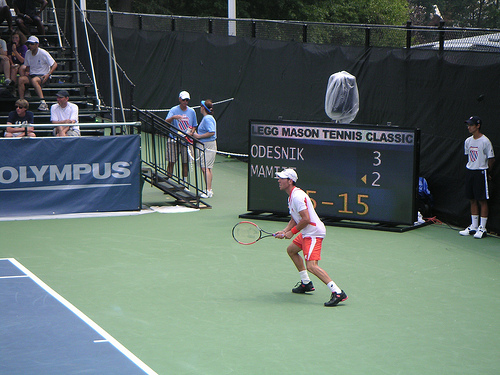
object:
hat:
[275, 168, 298, 183]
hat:
[178, 91, 190, 100]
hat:
[26, 35, 39, 43]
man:
[272, 166, 347, 308]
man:
[164, 89, 198, 192]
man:
[16, 35, 57, 110]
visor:
[201, 100, 212, 113]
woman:
[195, 98, 216, 198]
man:
[458, 114, 495, 240]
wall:
[54, 1, 500, 232]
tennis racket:
[231, 221, 286, 247]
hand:
[283, 230, 295, 239]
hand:
[275, 231, 286, 239]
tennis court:
[1, 131, 500, 375]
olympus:
[0, 161, 131, 185]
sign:
[0, 135, 141, 219]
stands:
[2, 1, 139, 136]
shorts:
[293, 233, 325, 261]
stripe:
[306, 237, 317, 259]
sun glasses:
[180, 98, 188, 102]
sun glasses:
[27, 42, 34, 46]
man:
[3, 99, 37, 138]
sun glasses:
[15, 105, 24, 109]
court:
[1, 116, 500, 373]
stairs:
[131, 105, 211, 209]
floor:
[0, 117, 500, 375]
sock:
[299, 270, 310, 284]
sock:
[327, 281, 340, 295]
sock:
[472, 214, 479, 228]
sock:
[481, 216, 487, 229]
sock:
[182, 174, 189, 185]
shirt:
[286, 187, 325, 238]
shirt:
[462, 135, 494, 172]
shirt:
[48, 103, 80, 130]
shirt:
[21, 47, 55, 76]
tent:
[404, 30, 499, 50]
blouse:
[198, 115, 218, 143]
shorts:
[197, 140, 218, 170]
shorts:
[164, 136, 191, 163]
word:
[249, 144, 305, 161]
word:
[249, 164, 297, 179]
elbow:
[300, 215, 310, 222]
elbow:
[209, 130, 215, 136]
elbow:
[52, 61, 57, 68]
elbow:
[6, 126, 12, 132]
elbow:
[28, 126, 34, 131]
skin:
[286, 209, 310, 238]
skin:
[305, 260, 330, 284]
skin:
[285, 242, 305, 273]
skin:
[15, 75, 46, 101]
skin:
[468, 198, 488, 217]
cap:
[464, 115, 482, 125]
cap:
[56, 90, 69, 97]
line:
[0, 257, 159, 375]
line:
[92, 338, 106, 344]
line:
[1, 274, 28, 278]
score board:
[246, 118, 419, 227]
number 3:
[372, 150, 382, 166]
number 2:
[371, 171, 381, 186]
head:
[275, 168, 298, 191]